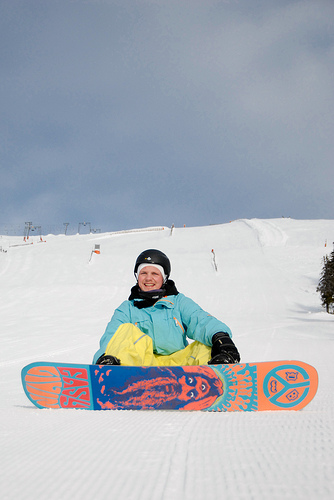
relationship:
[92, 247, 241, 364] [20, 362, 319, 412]
man with snowboard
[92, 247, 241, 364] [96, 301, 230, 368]
man wearing coat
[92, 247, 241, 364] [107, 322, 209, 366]
man wearing snowpants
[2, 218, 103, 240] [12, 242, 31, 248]
lift for skis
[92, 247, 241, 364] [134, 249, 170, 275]
man wearing helmet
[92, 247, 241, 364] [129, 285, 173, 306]
man wearing muffler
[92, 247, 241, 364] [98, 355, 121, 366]
man wearing boots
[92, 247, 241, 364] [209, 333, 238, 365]
man wearing glove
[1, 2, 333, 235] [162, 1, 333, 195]
sky has clouds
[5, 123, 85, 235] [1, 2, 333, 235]
clouds in sky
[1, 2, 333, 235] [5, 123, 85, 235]
sky has clouds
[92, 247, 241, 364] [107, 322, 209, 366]
man with snowpants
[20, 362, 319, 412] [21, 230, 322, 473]
snowboard in snow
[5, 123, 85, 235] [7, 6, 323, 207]
clouds in sky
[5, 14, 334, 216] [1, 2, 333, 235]
clouds in sky